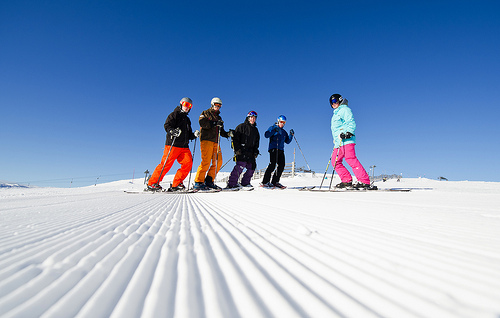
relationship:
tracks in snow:
[0, 192, 497, 317] [184, 202, 380, 280]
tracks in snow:
[2, 192, 497, 317] [1, 172, 498, 314]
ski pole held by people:
[306, 151, 347, 199] [327, 92, 371, 189]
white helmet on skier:
[204, 89, 250, 114] [190, 97, 234, 191]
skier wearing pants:
[190, 97, 234, 191] [194, 139, 225, 183]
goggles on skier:
[179, 100, 191, 112] [143, 91, 195, 195]